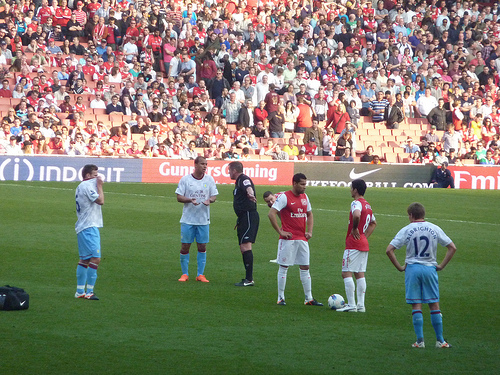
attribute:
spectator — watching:
[252, 120, 269, 139]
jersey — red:
[271, 190, 311, 238]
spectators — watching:
[0, 2, 485, 163]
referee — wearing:
[226, 160, 263, 290]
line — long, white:
[131, 182, 169, 209]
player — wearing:
[267, 171, 322, 306]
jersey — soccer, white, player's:
[373, 226, 468, 277]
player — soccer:
[333, 177, 379, 312]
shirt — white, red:
[270, 187, 316, 241]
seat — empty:
[362, 120, 374, 129]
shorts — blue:
[175, 229, 220, 272]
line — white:
[376, 206, 406, 220]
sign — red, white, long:
[4, 158, 499, 187]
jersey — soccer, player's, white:
[178, 177, 231, 220]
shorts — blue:
[176, 173, 227, 225]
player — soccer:
[264, 191, 285, 209]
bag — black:
[6, 280, 38, 315]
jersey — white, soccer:
[227, 175, 266, 247]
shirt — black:
[220, 172, 264, 215]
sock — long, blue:
[77, 250, 107, 300]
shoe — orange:
[171, 267, 197, 291]